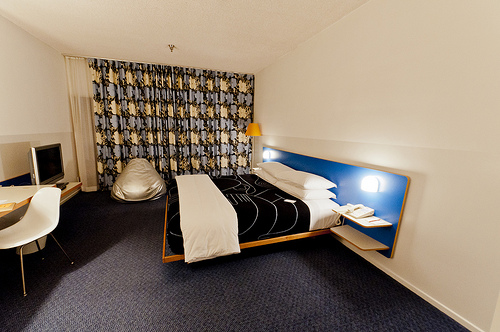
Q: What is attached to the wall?
A: Bed.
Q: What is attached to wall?
A: Headboard.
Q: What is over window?
A: Curtain.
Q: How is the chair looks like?
A: Round.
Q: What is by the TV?
A: Chair and desk.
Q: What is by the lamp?
A: Curtain on window.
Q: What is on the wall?
A: Headboard on bed.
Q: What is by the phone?
A: Made bed.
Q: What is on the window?
A: Drawn curtain.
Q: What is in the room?
A: Bed.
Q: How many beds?
A: 1.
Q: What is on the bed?
A: Pillows.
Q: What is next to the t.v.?
A: Desk.